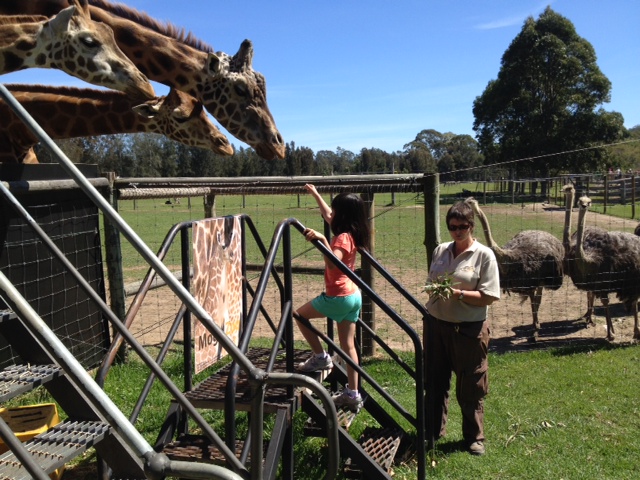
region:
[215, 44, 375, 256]
The girl is feeding the giraffe.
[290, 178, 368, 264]
The little girl is holding at the railing.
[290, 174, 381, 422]
The girl is going up the stairs.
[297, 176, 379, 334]
A little girl in a green shorts.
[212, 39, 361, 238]
The tall giraffe is eating.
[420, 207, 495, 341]
The zookeeper is holding a food.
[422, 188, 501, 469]
An adult woman standing.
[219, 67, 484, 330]
The zookeeper is helping the little girl feed the animals.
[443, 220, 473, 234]
dark black sunglasses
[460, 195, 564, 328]
a large ostrich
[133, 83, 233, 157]
the head of a giraffe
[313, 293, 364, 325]
a girl's green shorts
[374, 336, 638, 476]
a sectio of green grass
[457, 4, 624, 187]
a tall green tree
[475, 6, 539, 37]
a small white cloud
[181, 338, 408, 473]
an iron stairway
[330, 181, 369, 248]
a girl's black long hair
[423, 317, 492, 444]
a woman's brown pants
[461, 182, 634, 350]
three ostriches or emus in a large pen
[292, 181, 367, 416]
girl with black hair, green shorts and pink shirt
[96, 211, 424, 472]
black metal stairs with rails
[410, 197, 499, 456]
woman with short brown hair and sunglasses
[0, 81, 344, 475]
metal stairs with rails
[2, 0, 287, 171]
three giraffes in a pen reaching toward a girl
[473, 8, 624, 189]
large green trees on the side of a pen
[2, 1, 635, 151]
blue sky with sparse clouds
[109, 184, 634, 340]
fencing around an animal pen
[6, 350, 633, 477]
green grass near animal pens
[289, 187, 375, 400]
young girl feeding the giraffe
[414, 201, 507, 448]
woman wearing brown pants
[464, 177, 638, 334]
ostrichs behind the woman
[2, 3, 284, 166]
three giraffes leaning over the fence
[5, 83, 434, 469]
brown stairs and railings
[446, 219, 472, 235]
sunglasses woman is wearing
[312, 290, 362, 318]
green shorts girl is wearing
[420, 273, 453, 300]
green food woman is holding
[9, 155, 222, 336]
fencing in front of the giraffes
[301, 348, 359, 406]
shoes young girl is wearing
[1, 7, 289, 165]
Yellow and brown giraffes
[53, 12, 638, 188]
Green busy trees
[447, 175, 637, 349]
Brown ostriches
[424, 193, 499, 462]
A person wearing sunglasses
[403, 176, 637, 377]
Ostriches in a fenced pen.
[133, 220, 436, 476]
Black metal steps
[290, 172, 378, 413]
girl on the stairs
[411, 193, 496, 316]
woman holding food for the giraffes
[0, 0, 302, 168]
giraffes have their heads over the fence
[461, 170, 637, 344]
ostriches behind the zoo keeper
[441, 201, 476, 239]
woman is wearing sunglasses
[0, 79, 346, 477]
stairs on the side of the giraffes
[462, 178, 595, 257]
ostriches have long necks